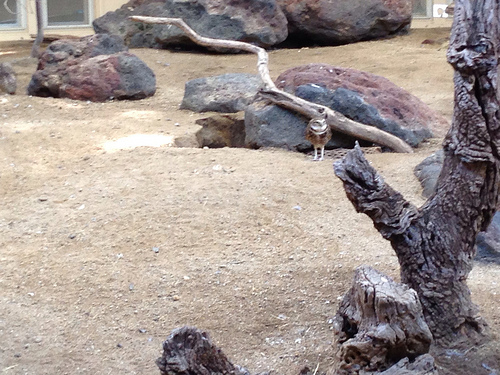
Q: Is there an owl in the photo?
A: Yes, there is an owl.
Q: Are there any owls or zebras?
A: Yes, there is an owl.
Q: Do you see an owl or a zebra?
A: Yes, there is an owl.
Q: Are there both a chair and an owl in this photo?
A: No, there is an owl but no chairs.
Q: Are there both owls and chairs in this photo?
A: No, there is an owl but no chairs.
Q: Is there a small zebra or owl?
A: Yes, there is a small owl.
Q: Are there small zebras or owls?
A: Yes, there is a small owl.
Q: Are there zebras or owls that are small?
A: Yes, the owl is small.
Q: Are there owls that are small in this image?
A: Yes, there is a small owl.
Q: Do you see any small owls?
A: Yes, there is a small owl.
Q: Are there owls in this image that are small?
A: Yes, there is an owl that is small.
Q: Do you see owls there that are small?
A: Yes, there is an owl that is small.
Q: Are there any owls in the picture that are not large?
A: Yes, there is a small owl.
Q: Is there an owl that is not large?
A: Yes, there is a small owl.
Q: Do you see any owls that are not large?
A: Yes, there is a small owl.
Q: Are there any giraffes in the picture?
A: No, there are no giraffes.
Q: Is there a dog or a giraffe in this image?
A: No, there are no giraffes or dogs.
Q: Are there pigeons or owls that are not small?
A: No, there is an owl but it is small.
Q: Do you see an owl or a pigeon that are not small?
A: No, there is an owl but it is small.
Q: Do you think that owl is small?
A: Yes, the owl is small.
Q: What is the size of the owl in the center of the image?
A: The owl is small.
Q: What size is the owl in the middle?
A: The owl is small.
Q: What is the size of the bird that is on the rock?
A: The owl is small.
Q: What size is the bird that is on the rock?
A: The owl is small.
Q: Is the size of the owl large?
A: No, the owl is small.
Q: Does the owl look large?
A: No, the owl is small.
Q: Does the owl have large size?
A: No, the owl is small.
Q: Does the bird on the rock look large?
A: No, the owl is small.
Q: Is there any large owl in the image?
A: No, there is an owl but it is small.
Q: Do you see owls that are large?
A: No, there is an owl but it is small.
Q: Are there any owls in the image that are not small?
A: No, there is an owl but it is small.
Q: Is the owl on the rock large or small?
A: The owl is small.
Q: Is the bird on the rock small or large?
A: The owl is small.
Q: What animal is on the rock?
A: The owl is on the rock.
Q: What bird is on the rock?
A: The bird is an owl.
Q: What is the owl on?
A: The owl is on the rock.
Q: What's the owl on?
A: The owl is on the rock.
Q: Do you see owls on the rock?
A: Yes, there is an owl on the rock.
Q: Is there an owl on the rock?
A: Yes, there is an owl on the rock.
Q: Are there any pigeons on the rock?
A: No, there is an owl on the rock.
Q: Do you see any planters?
A: No, there are no planters.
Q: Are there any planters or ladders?
A: No, there are no planters or ladders.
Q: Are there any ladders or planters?
A: No, there are no planters or ladders.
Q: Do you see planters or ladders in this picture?
A: No, there are no planters or ladders.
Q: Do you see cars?
A: No, there are no cars.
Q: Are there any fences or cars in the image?
A: No, there are no cars or fences.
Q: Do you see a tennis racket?
A: No, there are no rackets.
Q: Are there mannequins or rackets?
A: No, there are no rackets or mannequins.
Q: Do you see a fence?
A: No, there are no fences.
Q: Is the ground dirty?
A: Yes, the ground is dirty.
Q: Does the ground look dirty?
A: Yes, the ground is dirty.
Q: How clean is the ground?
A: The ground is dirty.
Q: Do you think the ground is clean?
A: No, the ground is dirty.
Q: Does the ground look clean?
A: No, the ground is dirty.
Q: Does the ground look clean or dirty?
A: The ground is dirty.